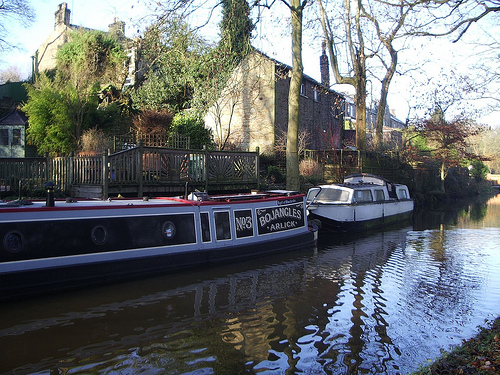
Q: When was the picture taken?
A: Daytime.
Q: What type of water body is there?
A: A canal.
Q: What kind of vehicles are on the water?
A: Boats.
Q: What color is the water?
A: Brown.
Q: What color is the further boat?
A: White.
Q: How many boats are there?
A: Two.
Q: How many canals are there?
A: One.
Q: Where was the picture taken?
A: On a river.